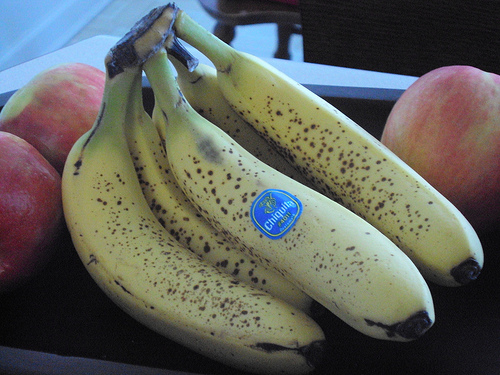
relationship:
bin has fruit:
[4, 31, 478, 368] [66, 52, 435, 329]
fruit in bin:
[66, 52, 435, 329] [4, 31, 478, 368]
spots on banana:
[71, 116, 372, 300] [218, 52, 485, 292]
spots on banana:
[71, 116, 372, 300] [56, 67, 324, 370]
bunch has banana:
[71, 3, 481, 373] [66, 0, 498, 375]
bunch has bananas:
[71, 3, 481, 373] [121, 66, 323, 321]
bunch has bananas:
[71, 3, 481, 373] [136, 47, 439, 346]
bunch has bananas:
[71, 3, 481, 373] [164, 41, 309, 183]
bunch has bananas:
[71, 3, 481, 373] [173, 12, 485, 287]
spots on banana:
[139, 228, 196, 300] [73, 139, 303, 362]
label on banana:
[241, 189, 312, 243] [142, 45, 436, 342]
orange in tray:
[380, 62, 497, 228] [1, 75, 498, 372]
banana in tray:
[142, 45, 436, 342] [1, 75, 498, 372]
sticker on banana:
[249, 189, 301, 239] [142, 45, 436, 342]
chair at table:
[195, 1, 309, 61] [292, 0, 499, 78]